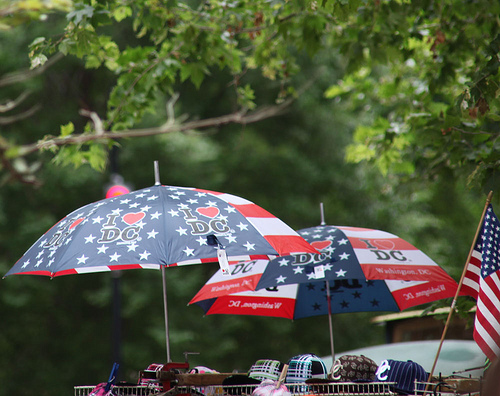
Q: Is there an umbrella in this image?
A: Yes, there are umbrellas.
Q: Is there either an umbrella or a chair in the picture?
A: Yes, there are umbrellas.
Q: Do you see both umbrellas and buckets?
A: No, there are umbrellas but no buckets.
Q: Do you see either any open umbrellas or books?
A: Yes, there are open umbrellas.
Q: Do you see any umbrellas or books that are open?
A: Yes, the umbrellas are open.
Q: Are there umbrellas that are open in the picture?
A: Yes, there are open umbrellas.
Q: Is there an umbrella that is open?
A: Yes, there are umbrellas that are open.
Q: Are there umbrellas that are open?
A: Yes, there are umbrellas that are open.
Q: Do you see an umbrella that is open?
A: Yes, there are umbrellas that are open.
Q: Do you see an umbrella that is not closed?
A: Yes, there are open umbrellas.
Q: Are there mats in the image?
A: No, there are no mats.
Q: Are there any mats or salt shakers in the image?
A: No, there are no mats or salt shakers.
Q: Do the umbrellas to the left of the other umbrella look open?
A: Yes, the umbrellas are open.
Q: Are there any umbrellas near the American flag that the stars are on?
A: Yes, there are umbrellas near the American flag.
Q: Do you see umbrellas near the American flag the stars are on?
A: Yes, there are umbrellas near the American flag.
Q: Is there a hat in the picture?
A: Yes, there is a hat.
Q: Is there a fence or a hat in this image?
A: Yes, there is a hat.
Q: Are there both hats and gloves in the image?
A: No, there is a hat but no gloves.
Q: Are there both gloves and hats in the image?
A: No, there is a hat but no gloves.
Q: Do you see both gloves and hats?
A: No, there is a hat but no gloves.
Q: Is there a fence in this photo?
A: No, there are no fences.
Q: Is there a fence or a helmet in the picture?
A: No, there are no fences or helmets.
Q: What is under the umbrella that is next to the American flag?
A: The hat is under the umbrella.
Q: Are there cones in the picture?
A: No, there are no cones.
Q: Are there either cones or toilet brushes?
A: No, there are no cones or toilet brushes.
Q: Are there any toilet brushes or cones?
A: No, there are no cones or toilet brushes.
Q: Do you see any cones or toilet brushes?
A: No, there are no cones or toilet brushes.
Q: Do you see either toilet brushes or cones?
A: No, there are no cones or toilet brushes.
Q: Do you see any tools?
A: No, there are no tools.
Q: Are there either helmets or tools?
A: No, there are no tools or helmets.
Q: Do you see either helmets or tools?
A: No, there are no tools or helmets.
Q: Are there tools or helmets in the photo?
A: No, there are no tools or helmets.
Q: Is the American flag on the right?
A: Yes, the American flag is on the right of the image.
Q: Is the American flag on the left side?
A: No, the American flag is on the right of the image.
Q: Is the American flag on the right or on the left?
A: The American flag is on the right of the image.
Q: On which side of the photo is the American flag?
A: The American flag is on the right of the image.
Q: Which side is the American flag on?
A: The American flag is on the right of the image.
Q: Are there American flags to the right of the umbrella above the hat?
A: Yes, there is an American flag to the right of the umbrella.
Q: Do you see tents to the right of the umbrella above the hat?
A: No, there is an American flag to the right of the umbrella.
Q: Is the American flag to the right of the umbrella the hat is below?
A: Yes, the American flag is to the right of the umbrella.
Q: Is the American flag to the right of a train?
A: No, the American flag is to the right of the umbrella.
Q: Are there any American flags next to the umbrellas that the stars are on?
A: Yes, there is an American flag next to the umbrellas.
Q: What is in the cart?
A: The American flag is in the cart.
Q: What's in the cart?
A: The American flag is in the cart.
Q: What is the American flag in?
A: The American flag is in the cart.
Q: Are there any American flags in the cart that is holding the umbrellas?
A: Yes, there is an American flag in the cart.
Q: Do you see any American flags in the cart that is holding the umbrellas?
A: Yes, there is an American flag in the cart.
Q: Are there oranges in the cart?
A: No, there is an American flag in the cart.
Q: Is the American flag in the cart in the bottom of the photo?
A: Yes, the American flag is in the cart.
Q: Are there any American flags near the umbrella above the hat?
A: Yes, there is an American flag near the umbrella.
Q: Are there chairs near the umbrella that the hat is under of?
A: No, there is an American flag near the umbrella.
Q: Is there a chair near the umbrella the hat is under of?
A: No, there is an American flag near the umbrella.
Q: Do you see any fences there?
A: No, there are no fences.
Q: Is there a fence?
A: No, there are no fences.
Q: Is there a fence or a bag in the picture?
A: No, there are no fences or bags.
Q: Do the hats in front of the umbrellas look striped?
A: Yes, the hats are striped.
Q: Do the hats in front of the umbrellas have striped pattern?
A: Yes, the hats are striped.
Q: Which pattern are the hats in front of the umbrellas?
A: The hats are striped.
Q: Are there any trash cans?
A: No, there are no trash cans.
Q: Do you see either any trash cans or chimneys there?
A: No, there are no trash cans or chimneys.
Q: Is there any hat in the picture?
A: Yes, there is a hat.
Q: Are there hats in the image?
A: Yes, there is a hat.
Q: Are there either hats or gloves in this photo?
A: Yes, there is a hat.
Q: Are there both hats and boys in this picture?
A: No, there is a hat but no boys.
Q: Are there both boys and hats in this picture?
A: No, there is a hat but no boys.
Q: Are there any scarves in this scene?
A: No, there are no scarves.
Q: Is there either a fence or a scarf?
A: No, there are no scarves or fences.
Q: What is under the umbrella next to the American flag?
A: The hat is under the umbrella.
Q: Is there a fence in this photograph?
A: No, there are no fences.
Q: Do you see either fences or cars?
A: No, there are no fences or cars.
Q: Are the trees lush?
A: Yes, the trees are lush.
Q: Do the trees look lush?
A: Yes, the trees are lush.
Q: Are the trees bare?
A: No, the trees are lush.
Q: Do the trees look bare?
A: No, the trees are lush.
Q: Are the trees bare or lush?
A: The trees are lush.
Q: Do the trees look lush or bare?
A: The trees are lush.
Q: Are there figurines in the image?
A: No, there are no figurines.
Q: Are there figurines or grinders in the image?
A: No, there are no figurines or grinders.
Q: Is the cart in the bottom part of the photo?
A: Yes, the cart is in the bottom of the image.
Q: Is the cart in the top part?
A: No, the cart is in the bottom of the image.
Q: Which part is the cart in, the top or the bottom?
A: The cart is in the bottom of the image.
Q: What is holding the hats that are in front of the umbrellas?
A: The cart is holding the hats.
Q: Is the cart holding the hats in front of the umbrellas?
A: Yes, the cart is holding the hats.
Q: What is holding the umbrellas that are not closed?
A: The cart is holding the umbrellas.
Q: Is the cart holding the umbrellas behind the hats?
A: Yes, the cart is holding the umbrellas.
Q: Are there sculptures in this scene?
A: No, there are no sculptures.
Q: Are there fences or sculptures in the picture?
A: No, there are no sculptures or fences.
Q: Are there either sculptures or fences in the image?
A: No, there are no sculptures or fences.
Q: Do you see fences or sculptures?
A: No, there are no sculptures or fences.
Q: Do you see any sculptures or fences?
A: No, there are no sculptures or fences.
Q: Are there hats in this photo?
A: Yes, there is a hat.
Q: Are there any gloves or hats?
A: Yes, there is a hat.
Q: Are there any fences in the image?
A: No, there are no fences.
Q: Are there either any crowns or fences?
A: No, there are no fences or crowns.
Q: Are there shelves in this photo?
A: No, there are no shelves.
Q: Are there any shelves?
A: No, there are no shelves.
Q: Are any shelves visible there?
A: No, there are no shelves.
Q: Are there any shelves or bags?
A: No, there are no shelves or bags.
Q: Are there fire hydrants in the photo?
A: No, there are no fire hydrants.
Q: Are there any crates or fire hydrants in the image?
A: No, there are no fire hydrants or crates.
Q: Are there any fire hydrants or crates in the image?
A: No, there are no fire hydrants or crates.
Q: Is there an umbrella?
A: Yes, there is an umbrella.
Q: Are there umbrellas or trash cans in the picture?
A: Yes, there is an umbrella.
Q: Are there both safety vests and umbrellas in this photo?
A: No, there is an umbrella but no safety jackets.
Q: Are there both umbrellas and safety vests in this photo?
A: No, there is an umbrella but no safety jackets.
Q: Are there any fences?
A: No, there are no fences.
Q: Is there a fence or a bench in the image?
A: No, there are no fences or benches.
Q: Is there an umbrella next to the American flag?
A: Yes, there is an umbrella next to the American flag.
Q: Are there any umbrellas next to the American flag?
A: Yes, there is an umbrella next to the American flag.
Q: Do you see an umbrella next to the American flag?
A: Yes, there is an umbrella next to the American flag.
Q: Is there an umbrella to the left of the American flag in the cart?
A: Yes, there is an umbrella to the left of the American flag.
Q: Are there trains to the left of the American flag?
A: No, there is an umbrella to the left of the American flag.